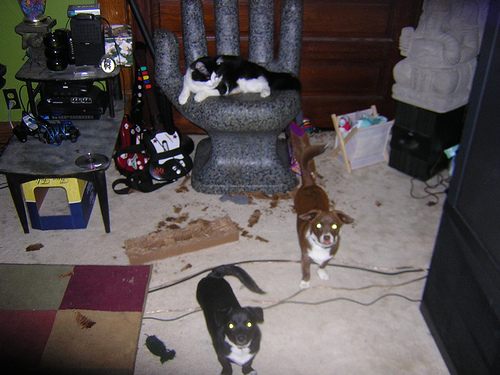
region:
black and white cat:
[183, 47, 286, 110]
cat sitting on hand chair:
[177, 50, 270, 117]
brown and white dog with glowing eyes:
[296, 197, 359, 288]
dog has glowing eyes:
[226, 318, 278, 338]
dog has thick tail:
[208, 253, 279, 313]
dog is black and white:
[202, 285, 274, 357]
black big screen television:
[445, 210, 481, 345]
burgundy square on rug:
[81, 251, 116, 319]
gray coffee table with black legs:
[18, 152, 106, 197]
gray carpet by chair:
[329, 322, 392, 348]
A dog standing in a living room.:
[250, 118, 404, 285]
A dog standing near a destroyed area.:
[180, 249, 275, 372]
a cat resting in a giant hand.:
[138, 3, 320, 208]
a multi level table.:
[0, 2, 147, 237]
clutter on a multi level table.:
[10, 0, 135, 155]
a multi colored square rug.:
[0, 245, 169, 373]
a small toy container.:
[329, 85, 400, 190]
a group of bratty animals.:
[134, 23, 374, 371]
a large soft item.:
[370, 4, 496, 106]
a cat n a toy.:
[155, 48, 302, 114]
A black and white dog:
[194, 262, 264, 374]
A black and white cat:
[178, 48, 303, 107]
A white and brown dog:
[284, 145, 351, 285]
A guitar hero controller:
[133, 56, 197, 187]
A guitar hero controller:
[116, 73, 145, 175]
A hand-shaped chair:
[154, 3, 304, 192]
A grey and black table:
[2, 98, 127, 235]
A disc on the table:
[73, 147, 108, 172]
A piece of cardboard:
[124, 211, 237, 263]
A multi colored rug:
[2, 264, 151, 374]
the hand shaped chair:
[152, 0, 305, 198]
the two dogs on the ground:
[195, 138, 358, 373]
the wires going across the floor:
[140, 238, 435, 329]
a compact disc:
[73, 150, 108, 170]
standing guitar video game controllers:
[116, 28, 201, 194]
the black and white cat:
[175, 53, 297, 110]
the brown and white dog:
[288, 139, 353, 286]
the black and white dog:
[190, 263, 276, 374]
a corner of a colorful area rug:
[5, 255, 158, 372]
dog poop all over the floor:
[152, 169, 309, 270]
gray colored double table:
[7, 37, 125, 243]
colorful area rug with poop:
[37, 247, 120, 373]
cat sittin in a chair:
[184, 51, 287, 98]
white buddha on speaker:
[408, 3, 449, 121]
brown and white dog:
[286, 129, 353, 270]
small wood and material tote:
[319, 107, 400, 173]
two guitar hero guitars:
[97, 43, 191, 179]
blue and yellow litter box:
[28, 176, 108, 235]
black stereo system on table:
[35, 92, 128, 128]